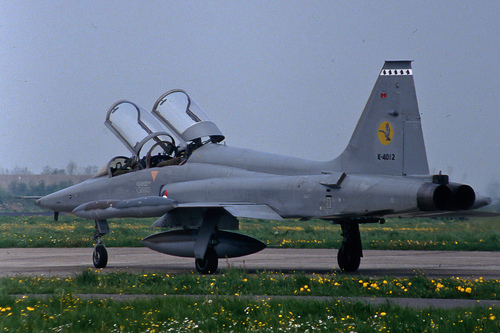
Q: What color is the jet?
A: Grey.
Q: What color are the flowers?
A: Yellow & white.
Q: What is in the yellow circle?
A: A bird.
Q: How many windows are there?
A: Two.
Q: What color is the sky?
A: Blue.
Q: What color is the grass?
A: Green.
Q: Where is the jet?
A: On the ground.